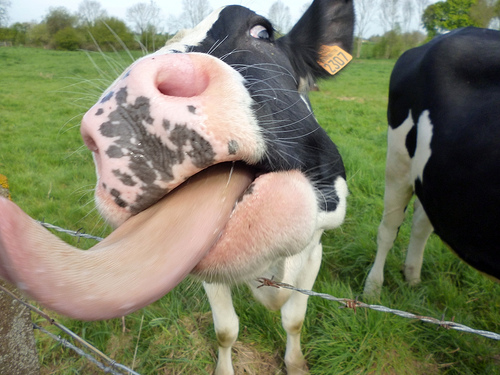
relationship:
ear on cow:
[277, 0, 356, 83] [0, 0, 360, 374]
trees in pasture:
[31, 15, 139, 60] [20, 52, 84, 172]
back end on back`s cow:
[361, 42, 432, 299] [361, 25, 499, 301]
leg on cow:
[256, 257, 324, 372] [27, 18, 418, 340]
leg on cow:
[198, 281, 243, 374] [0, 0, 360, 374]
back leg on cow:
[369, 120, 412, 274] [358, 25, 496, 326]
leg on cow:
[278, 243, 322, 373] [79, 1, 347, 275]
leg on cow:
[198, 278, 243, 374] [79, 1, 347, 275]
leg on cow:
[404, 199, 435, 286] [358, 25, 496, 326]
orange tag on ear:
[315, 41, 355, 77] [284, 1, 364, 83]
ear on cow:
[284, 1, 364, 83] [78, 19, 411, 361]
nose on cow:
[79, 51, 229, 181] [70, 2, 371, 372]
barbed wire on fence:
[255, 275, 497, 340] [257, 275, 497, 341]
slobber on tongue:
[219, 153, 239, 204] [87, 215, 214, 322]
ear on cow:
[277, 0, 356, 83] [60, 31, 359, 339]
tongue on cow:
[0, 170, 252, 321] [0, 0, 360, 374]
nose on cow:
[79, 51, 229, 181] [0, 0, 360, 374]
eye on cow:
[246, 23, 273, 44] [81, 23, 396, 335]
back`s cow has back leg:
[361, 25, 499, 301] [350, 120, 412, 307]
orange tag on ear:
[315, 41, 355, 77] [290, 0, 356, 100]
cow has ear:
[0, 0, 360, 374] [290, 0, 356, 100]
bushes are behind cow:
[0, 0, 439, 61] [0, 0, 360, 374]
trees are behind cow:
[416, 0, 497, 36] [0, 0, 360, 374]